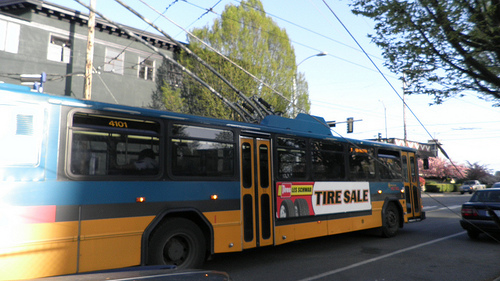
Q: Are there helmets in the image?
A: No, there are no helmets.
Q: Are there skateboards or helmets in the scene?
A: No, there are no helmets or skateboards.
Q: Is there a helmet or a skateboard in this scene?
A: No, there are no helmets or skateboards.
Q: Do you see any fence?
A: No, there are no fences.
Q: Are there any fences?
A: No, there are no fences.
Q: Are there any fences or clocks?
A: No, there are no fences or clocks.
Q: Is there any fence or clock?
A: No, there are no fences or clocks.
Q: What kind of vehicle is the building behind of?
A: The building is behind the bus.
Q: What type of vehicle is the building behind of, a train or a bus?
A: The building is behind a bus.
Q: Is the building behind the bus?
A: Yes, the building is behind the bus.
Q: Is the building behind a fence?
A: No, the building is behind the bus.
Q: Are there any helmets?
A: No, there are no helmets.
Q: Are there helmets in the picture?
A: No, there are no helmets.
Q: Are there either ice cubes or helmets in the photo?
A: No, there are no helmets or ice cubes.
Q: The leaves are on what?
A: The leaves are on the tree.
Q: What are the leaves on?
A: The leaves are on the tree.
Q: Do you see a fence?
A: No, there are no fences.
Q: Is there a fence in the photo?
A: No, there are no fences.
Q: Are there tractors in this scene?
A: No, there are no tractors.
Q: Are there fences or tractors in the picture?
A: No, there are no tractors or fences.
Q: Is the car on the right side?
A: Yes, the car is on the right of the image.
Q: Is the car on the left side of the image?
A: No, the car is on the right of the image.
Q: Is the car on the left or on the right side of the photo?
A: The car is on the right of the image.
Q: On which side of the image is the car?
A: The car is on the right of the image.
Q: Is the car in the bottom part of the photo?
A: Yes, the car is in the bottom of the image.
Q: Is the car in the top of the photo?
A: No, the car is in the bottom of the image.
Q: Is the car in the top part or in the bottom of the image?
A: The car is in the bottom of the image.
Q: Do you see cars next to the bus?
A: Yes, there is a car next to the bus.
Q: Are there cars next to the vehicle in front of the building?
A: Yes, there is a car next to the bus.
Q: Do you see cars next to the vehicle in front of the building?
A: Yes, there is a car next to the bus.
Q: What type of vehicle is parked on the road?
A: The vehicle is a car.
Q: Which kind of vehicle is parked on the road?
A: The vehicle is a car.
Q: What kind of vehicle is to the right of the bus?
A: The vehicle is a car.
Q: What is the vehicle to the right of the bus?
A: The vehicle is a car.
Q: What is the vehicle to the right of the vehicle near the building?
A: The vehicle is a car.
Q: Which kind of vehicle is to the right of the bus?
A: The vehicle is a car.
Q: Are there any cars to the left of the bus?
A: No, the car is to the right of the bus.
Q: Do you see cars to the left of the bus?
A: No, the car is to the right of the bus.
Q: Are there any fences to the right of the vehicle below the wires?
A: No, there is a car to the right of the bus.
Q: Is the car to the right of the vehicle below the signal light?
A: Yes, the car is to the right of the bus.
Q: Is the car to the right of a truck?
A: No, the car is to the right of the bus.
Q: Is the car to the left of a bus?
A: No, the car is to the right of a bus.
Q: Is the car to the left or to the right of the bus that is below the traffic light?
A: The car is to the right of the bus.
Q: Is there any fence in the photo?
A: No, there are no fences.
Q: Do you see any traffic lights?
A: Yes, there is a traffic light.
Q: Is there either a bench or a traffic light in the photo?
A: Yes, there is a traffic light.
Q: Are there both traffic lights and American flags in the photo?
A: No, there is a traffic light but no American flags.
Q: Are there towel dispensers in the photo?
A: No, there are no towel dispensers.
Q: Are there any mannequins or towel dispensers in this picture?
A: No, there are no towel dispensers or mannequins.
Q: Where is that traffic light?
A: The traffic light is on the road.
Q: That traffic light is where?
A: The traffic light is on the road.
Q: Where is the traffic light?
A: The traffic light is on the road.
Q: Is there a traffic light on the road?
A: Yes, there is a traffic light on the road.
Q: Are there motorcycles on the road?
A: No, there is a traffic light on the road.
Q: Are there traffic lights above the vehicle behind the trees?
A: Yes, there is a traffic light above the bus.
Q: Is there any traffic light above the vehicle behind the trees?
A: Yes, there is a traffic light above the bus.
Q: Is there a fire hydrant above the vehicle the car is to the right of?
A: No, there is a traffic light above the bus.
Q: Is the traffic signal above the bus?
A: Yes, the traffic signal is above the bus.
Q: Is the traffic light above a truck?
A: No, the traffic light is above the bus.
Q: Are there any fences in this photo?
A: No, there are no fences.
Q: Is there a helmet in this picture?
A: No, there are no helmets.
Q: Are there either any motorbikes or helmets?
A: No, there are no helmets or motorbikes.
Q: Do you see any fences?
A: No, there are no fences.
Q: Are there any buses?
A: Yes, there is a bus.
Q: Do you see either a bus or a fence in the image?
A: Yes, there is a bus.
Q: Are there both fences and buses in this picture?
A: No, there is a bus but no fences.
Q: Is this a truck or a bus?
A: This is a bus.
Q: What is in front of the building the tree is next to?
A: The bus is in front of the building.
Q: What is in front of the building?
A: The bus is in front of the building.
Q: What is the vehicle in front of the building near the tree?
A: The vehicle is a bus.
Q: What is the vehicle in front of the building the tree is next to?
A: The vehicle is a bus.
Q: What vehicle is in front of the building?
A: The vehicle is a bus.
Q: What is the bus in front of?
A: The bus is in front of the building.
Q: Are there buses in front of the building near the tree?
A: Yes, there is a bus in front of the building.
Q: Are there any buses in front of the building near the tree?
A: Yes, there is a bus in front of the building.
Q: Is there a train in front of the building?
A: No, there is a bus in front of the building.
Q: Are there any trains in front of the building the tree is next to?
A: No, there is a bus in front of the building.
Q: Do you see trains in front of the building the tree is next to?
A: No, there is a bus in front of the building.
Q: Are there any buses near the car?
A: Yes, there is a bus near the car.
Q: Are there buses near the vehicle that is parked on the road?
A: Yes, there is a bus near the car.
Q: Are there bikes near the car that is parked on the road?
A: No, there is a bus near the car.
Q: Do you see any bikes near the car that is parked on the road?
A: No, there is a bus near the car.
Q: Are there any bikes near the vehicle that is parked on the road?
A: No, there is a bus near the car.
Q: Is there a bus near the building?
A: Yes, there is a bus near the building.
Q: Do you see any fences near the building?
A: No, there is a bus near the building.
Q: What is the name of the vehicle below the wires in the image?
A: The vehicle is a bus.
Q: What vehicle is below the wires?
A: The vehicle is a bus.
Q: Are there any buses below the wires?
A: Yes, there is a bus below the wires.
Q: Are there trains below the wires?
A: No, there is a bus below the wires.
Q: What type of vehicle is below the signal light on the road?
A: The vehicle is a bus.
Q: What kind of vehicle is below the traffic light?
A: The vehicle is a bus.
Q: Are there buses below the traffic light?
A: Yes, there is a bus below the traffic light.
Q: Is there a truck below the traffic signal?
A: No, there is a bus below the traffic signal.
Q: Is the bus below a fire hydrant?
A: No, the bus is below the signal light.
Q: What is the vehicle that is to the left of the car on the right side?
A: The vehicle is a bus.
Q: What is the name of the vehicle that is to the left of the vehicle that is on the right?
A: The vehicle is a bus.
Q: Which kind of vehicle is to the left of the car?
A: The vehicle is a bus.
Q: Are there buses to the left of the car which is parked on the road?
A: Yes, there is a bus to the left of the car.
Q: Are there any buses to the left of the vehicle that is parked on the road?
A: Yes, there is a bus to the left of the car.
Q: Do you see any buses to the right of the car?
A: No, the bus is to the left of the car.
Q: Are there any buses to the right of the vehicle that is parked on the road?
A: No, the bus is to the left of the car.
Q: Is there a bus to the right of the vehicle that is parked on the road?
A: No, the bus is to the left of the car.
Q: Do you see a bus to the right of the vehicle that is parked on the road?
A: No, the bus is to the left of the car.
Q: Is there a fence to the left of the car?
A: No, there is a bus to the left of the car.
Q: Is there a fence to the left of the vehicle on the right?
A: No, there is a bus to the left of the car.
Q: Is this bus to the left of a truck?
A: No, the bus is to the left of the car.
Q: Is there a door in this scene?
A: Yes, there is a door.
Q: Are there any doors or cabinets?
A: Yes, there is a door.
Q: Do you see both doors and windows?
A: Yes, there are both a door and a window.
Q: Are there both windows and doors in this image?
A: Yes, there are both a door and a window.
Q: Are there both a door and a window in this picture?
A: Yes, there are both a door and a window.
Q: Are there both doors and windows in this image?
A: Yes, there are both a door and a window.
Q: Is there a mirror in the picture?
A: No, there are no mirrors.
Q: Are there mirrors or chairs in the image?
A: No, there are no mirrors or chairs.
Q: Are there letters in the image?
A: Yes, there are letters.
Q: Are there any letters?
A: Yes, there are letters.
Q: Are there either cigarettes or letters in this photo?
A: Yes, there are letters.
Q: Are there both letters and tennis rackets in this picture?
A: No, there are letters but no rackets.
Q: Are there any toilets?
A: No, there are no toilets.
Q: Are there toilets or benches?
A: No, there are no toilets or benches.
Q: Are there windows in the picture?
A: Yes, there is a window.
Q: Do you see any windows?
A: Yes, there is a window.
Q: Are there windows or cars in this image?
A: Yes, there is a window.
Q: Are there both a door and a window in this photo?
A: Yes, there are both a window and a door.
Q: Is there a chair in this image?
A: No, there are no chairs.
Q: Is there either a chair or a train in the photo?
A: No, there are no chairs or trains.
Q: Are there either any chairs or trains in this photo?
A: No, there are no chairs or trains.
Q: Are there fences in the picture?
A: No, there are no fences.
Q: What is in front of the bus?
A: The trees are in front of the bus.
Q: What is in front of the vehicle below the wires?
A: The trees are in front of the bus.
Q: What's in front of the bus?
A: The trees are in front of the bus.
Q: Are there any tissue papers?
A: No, there are no tissue papers.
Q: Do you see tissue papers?
A: No, there are no tissue papers.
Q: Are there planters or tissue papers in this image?
A: No, there are no tissue papers or planters.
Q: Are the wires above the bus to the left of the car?
A: Yes, the wires are above the bus.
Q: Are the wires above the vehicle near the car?
A: Yes, the wires are above the bus.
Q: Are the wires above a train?
A: No, the wires are above the bus.